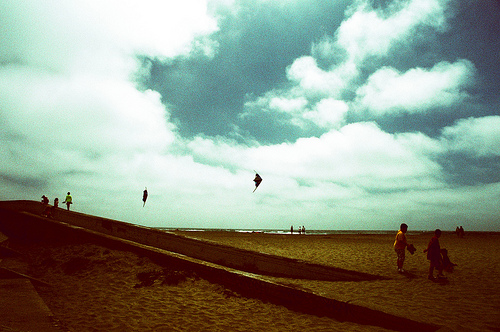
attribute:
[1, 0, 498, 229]
sky — blue, cloudy, white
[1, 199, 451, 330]
hill — concrete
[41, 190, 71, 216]
people — standing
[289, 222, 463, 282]
people — walking, together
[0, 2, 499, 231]
clouds — white